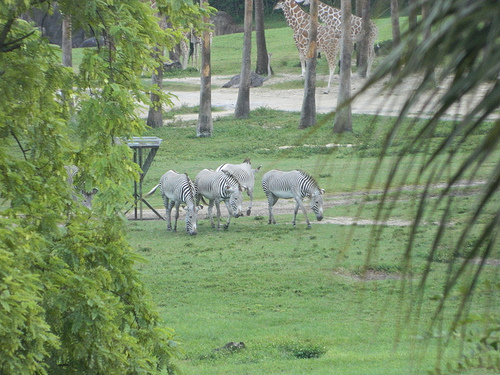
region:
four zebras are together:
[98, 135, 341, 232]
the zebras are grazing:
[130, 170, 322, 225]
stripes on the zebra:
[265, 170, 300, 186]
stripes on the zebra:
[230, 168, 254, 183]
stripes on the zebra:
[194, 172, 233, 187]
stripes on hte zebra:
[152, 168, 187, 199]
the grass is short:
[202, 261, 284, 298]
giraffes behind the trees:
[263, 14, 361, 73]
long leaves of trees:
[360, 24, 487, 229]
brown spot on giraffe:
[286, 0, 296, 7]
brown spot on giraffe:
[289, 18, 296, 25]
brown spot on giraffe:
[296, 23, 302, 35]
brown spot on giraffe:
[301, 25, 307, 39]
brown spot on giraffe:
[297, 33, 304, 43]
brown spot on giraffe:
[319, 1, 329, 8]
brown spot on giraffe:
[320, 10, 329, 15]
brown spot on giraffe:
[317, 28, 325, 38]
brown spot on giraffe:
[296, 40, 304, 51]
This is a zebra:
[256, 156, 346, 238]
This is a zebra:
[159, 160, 201, 258]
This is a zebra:
[189, 161, 260, 242]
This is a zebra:
[216, 150, 273, 189]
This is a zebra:
[261, 161, 340, 244]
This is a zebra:
[163, 170, 213, 267]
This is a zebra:
[255, 164, 342, 228]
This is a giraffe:
[304, 1, 399, 85]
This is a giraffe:
[286, 0, 358, 101]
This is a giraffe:
[303, 0, 387, 88]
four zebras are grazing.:
[160, 163, 328, 235]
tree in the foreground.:
[6, 2, 196, 372]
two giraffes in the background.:
[276, 0, 373, 94]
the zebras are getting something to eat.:
[155, 161, 325, 236]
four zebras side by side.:
[156, 163, 326, 231]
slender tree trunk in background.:
[235, 0, 255, 117]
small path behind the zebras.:
[96, 180, 482, 210]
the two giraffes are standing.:
[275, 0, 371, 97]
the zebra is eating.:
[146, 170, 202, 237]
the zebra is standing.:
[258, 170, 323, 231]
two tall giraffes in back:
[275, 3, 375, 97]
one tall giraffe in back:
[277, 1, 338, 86]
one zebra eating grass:
[268, 145, 352, 247]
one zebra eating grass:
[227, 146, 262, 230]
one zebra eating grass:
[200, 149, 238, 244]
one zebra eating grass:
[158, 165, 199, 236]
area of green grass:
[218, 275, 292, 343]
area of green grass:
[174, 279, 196, 317]